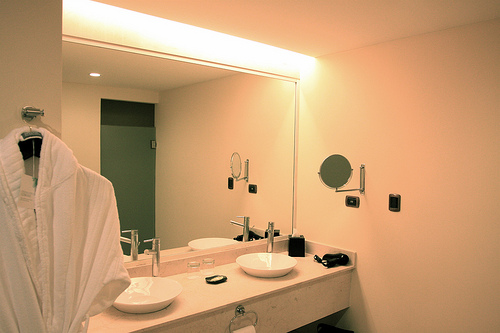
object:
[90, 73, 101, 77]
light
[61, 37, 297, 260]
mirror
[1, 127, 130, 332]
robe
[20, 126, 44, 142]
hanger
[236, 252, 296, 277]
double sinks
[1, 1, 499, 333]
bathroom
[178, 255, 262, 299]
vanity counter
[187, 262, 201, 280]
cups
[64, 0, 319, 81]
light fixture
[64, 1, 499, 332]
wall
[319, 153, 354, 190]
mirror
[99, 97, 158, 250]
green door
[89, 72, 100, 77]
reflection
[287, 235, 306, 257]
tissue box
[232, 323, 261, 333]
roll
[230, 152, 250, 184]
magnifier mirror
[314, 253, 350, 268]
hair dryer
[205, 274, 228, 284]
soap dish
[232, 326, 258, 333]
toilet paper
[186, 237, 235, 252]
white sink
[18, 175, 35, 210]
tag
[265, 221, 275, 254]
faucets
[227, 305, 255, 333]
toilet holder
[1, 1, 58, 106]
wall